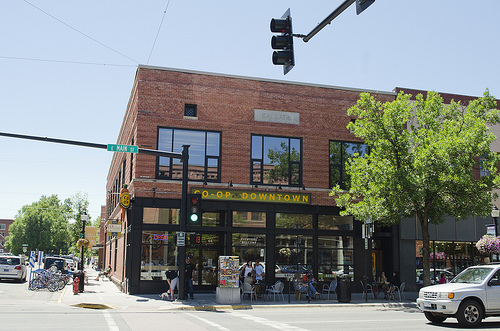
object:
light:
[270, 34, 289, 50]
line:
[103, 310, 121, 330]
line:
[184, 312, 231, 330]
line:
[228, 312, 308, 330]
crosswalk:
[101, 308, 312, 331]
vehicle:
[415, 264, 500, 328]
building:
[94, 61, 499, 298]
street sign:
[106, 143, 139, 153]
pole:
[0, 131, 183, 160]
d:
[242, 192, 249, 199]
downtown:
[242, 192, 309, 203]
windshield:
[450, 267, 494, 283]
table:
[252, 283, 270, 301]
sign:
[190, 187, 312, 205]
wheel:
[456, 298, 485, 328]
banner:
[192, 189, 310, 203]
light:
[190, 213, 200, 222]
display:
[217, 255, 240, 288]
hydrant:
[73, 276, 81, 295]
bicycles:
[29, 270, 61, 292]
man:
[164, 269, 179, 301]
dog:
[159, 290, 172, 301]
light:
[269, 17, 288, 34]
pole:
[302, 0, 355, 43]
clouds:
[158, 30, 183, 44]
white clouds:
[1, 162, 42, 191]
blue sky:
[0, 0, 497, 220]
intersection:
[0, 289, 188, 330]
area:
[0, 0, 500, 331]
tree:
[327, 83, 500, 286]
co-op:
[194, 189, 232, 198]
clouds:
[51, 170, 86, 186]